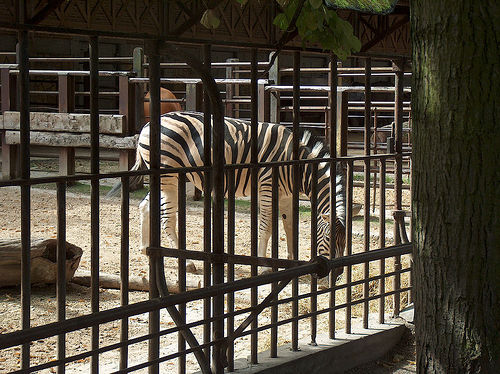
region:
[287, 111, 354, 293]
the zebra is eating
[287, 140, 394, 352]
the zebra is eating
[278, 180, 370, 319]
the zebra is eating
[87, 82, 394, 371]
the zebra is stripes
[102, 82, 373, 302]
a zebra behind bars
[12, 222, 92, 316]
part of a large log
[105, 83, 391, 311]
a black and white zebra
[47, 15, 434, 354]
a black fence in front of zebra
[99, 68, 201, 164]
another animal in a pen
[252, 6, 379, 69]
some green leaves at the top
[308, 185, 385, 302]
a head of a zebra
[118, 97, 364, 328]
a grazing zebra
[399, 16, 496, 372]
a large tree trunk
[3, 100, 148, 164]
large wooden slats on fence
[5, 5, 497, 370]
zebra in an enclosure in a zoo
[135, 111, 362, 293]
zebra in the cage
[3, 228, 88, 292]
wooden log on the ground in the enclosure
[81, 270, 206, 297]
wooden log on the ground in the enclosure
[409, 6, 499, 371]
tree outside of the zebra enclosure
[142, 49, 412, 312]
bars of the zebra enclosure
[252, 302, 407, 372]
concrete setting for the bars of the zebra enclosure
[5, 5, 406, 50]
trees in the background behind the zebra enclosure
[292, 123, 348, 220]
black and white mane of the zebra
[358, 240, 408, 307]
short dried grass in the zebra enclosure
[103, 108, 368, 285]
the zebra is black and white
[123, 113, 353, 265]
the zebra is grazing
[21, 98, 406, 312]
the bars are metallic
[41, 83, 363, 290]
the bars are black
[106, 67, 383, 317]
the poles are made of iron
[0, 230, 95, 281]
the log is on the ground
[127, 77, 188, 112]
the horse is brown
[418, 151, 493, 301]
the treebark is grey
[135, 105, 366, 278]
the zebra is indoors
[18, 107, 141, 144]
the bars are grey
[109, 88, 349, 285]
a zebra bent down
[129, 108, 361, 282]
a zebra in a cage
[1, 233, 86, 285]
a log in the cage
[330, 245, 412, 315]
hay that the zebra is eating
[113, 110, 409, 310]
a zebra eating hay off the ground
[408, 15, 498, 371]
the large trunk of a tree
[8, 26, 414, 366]
the wire rods of the cage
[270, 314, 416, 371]
cement curb of the cage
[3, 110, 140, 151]
wood alongside of the cage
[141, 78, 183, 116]
a brown horse in the background